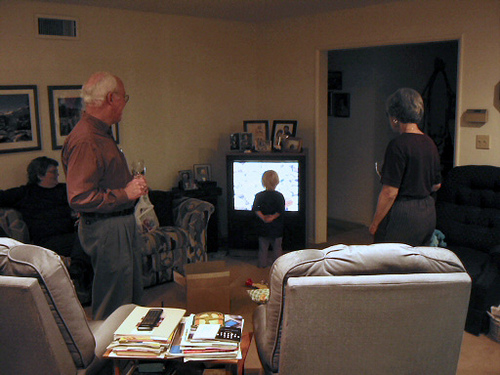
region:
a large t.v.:
[226, 157, 306, 246]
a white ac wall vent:
[31, 14, 83, 39]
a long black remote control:
[134, 303, 166, 331]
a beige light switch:
[473, 133, 489, 150]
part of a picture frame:
[0, 84, 45, 154]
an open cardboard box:
[167, 257, 235, 313]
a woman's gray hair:
[382, 88, 428, 125]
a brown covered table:
[95, 327, 255, 374]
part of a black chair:
[435, 164, 498, 335]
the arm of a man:
[66, 140, 131, 215]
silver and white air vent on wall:
[24, 8, 101, 48]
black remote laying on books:
[135, 300, 167, 332]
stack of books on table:
[178, 308, 249, 359]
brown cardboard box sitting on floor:
[167, 254, 244, 316]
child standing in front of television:
[243, 165, 307, 263]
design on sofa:
[172, 213, 207, 258]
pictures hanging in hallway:
[321, 65, 360, 121]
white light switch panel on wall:
[469, 129, 493, 151]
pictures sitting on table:
[164, 149, 217, 193]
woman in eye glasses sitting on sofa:
[11, 140, 66, 252]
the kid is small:
[243, 165, 288, 270]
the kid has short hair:
[254, 166, 287, 188]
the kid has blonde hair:
[256, 164, 289, 191]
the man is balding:
[76, 69, 136, 114]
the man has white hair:
[73, 70, 130, 111]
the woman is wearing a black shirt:
[376, 130, 446, 199]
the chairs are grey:
[1, 218, 479, 370]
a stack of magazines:
[93, 295, 248, 373]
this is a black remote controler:
[128, 305, 169, 334]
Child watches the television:
[252, 170, 285, 270]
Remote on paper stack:
[138, 308, 164, 330]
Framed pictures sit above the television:
[226, 118, 301, 156]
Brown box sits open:
[171, 258, 243, 313]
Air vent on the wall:
[33, 14, 80, 40]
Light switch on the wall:
[474, 132, 489, 149]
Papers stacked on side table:
[103, 304, 245, 362]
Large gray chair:
[253, 242, 473, 374]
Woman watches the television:
[367, 87, 444, 246]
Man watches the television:
[58, 69, 147, 317]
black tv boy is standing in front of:
[225, 153, 305, 253]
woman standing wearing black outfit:
[366, 92, 457, 243]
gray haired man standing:
[65, 71, 146, 300]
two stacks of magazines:
[105, 300, 246, 360]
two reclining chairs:
[0, 229, 476, 366]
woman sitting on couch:
[22, 160, 87, 295]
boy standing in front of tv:
[249, 165, 291, 265]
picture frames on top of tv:
[229, 110, 299, 152]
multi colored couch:
[2, 180, 214, 291]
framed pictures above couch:
[2, 83, 121, 163]